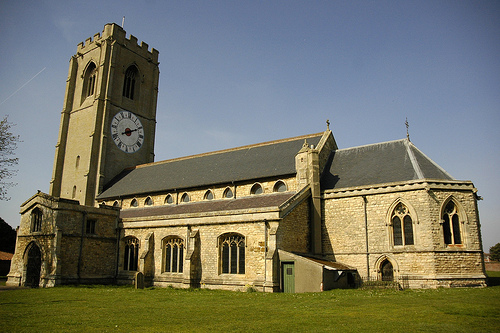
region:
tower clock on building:
[108, 104, 154, 171]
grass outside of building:
[81, 282, 136, 326]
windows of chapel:
[210, 236, 254, 286]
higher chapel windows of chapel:
[80, 62, 105, 104]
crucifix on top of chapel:
[381, 91, 432, 148]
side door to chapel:
[279, 263, 309, 299]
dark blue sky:
[171, 48, 283, 112]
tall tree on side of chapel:
[1, 123, 26, 193]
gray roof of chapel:
[171, 150, 276, 183]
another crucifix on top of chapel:
[323, 113, 343, 136]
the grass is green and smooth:
[7, 292, 487, 324]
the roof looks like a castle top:
[71, 16, 164, 63]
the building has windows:
[379, 197, 479, 259]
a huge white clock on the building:
[107, 105, 146, 156]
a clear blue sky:
[175, 10, 482, 103]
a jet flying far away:
[11, 54, 53, 99]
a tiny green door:
[279, 260, 306, 292]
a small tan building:
[26, 25, 484, 287]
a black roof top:
[130, 138, 425, 178]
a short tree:
[2, 113, 22, 208]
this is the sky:
[165, 10, 429, 94]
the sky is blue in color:
[241, 45, 301, 78]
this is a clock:
[113, 115, 141, 154]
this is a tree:
[2, 124, 16, 186]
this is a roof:
[336, 147, 391, 182]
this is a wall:
[323, 202, 375, 259]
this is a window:
[392, 215, 413, 245]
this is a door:
[282, 263, 293, 295]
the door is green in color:
[284, 277, 291, 286]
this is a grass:
[96, 290, 203, 318]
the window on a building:
[216, 232, 246, 273]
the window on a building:
[161, 234, 185, 272]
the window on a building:
[121, 236, 144, 268]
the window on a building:
[387, 201, 417, 243]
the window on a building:
[439, 197, 465, 240]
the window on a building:
[381, 258, 396, 280]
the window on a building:
[33, 210, 45, 234]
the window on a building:
[86, 218, 101, 233]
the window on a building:
[117, 60, 144, 97]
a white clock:
[111, 107, 151, 152]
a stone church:
[8, 13, 495, 300]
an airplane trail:
[0, 60, 60, 112]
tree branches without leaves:
[0, 110, 25, 213]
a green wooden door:
[274, 251, 308, 296]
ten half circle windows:
[95, 177, 289, 207]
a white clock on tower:
[42, 19, 162, 207]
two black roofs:
[95, 131, 455, 201]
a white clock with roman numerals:
[107, 100, 146, 162]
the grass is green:
[0, 268, 498, 331]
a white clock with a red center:
[105, 103, 153, 161]